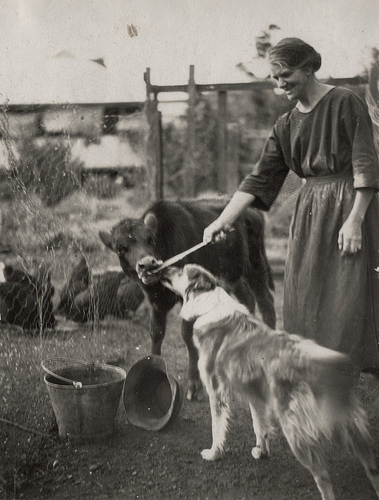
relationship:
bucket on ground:
[40, 354, 125, 441] [35, 427, 223, 497]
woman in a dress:
[200, 37, 377, 375] [236, 83, 378, 373]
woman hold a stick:
[200, 37, 377, 375] [143, 238, 219, 296]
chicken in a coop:
[67, 272, 124, 322] [8, 210, 144, 356]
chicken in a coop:
[112, 277, 145, 318] [8, 210, 144, 356]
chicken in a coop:
[53, 256, 94, 317] [8, 210, 144, 356]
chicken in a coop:
[0, 262, 60, 296] [8, 210, 144, 356]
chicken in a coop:
[2, 275, 53, 329] [8, 210, 144, 356]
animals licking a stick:
[159, 262, 378, 499] [152, 237, 227, 290]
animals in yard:
[159, 262, 378, 499] [81, 420, 246, 494]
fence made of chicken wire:
[77, 36, 250, 149] [18, 223, 146, 339]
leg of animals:
[196, 383, 235, 464] [159, 262, 378, 499]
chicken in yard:
[0, 281, 58, 333] [4, 199, 156, 379]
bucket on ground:
[40, 354, 125, 441] [31, 449, 201, 486]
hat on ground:
[124, 352, 183, 428] [31, 449, 201, 486]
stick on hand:
[153, 228, 235, 275] [198, 220, 231, 247]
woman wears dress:
[199, 28, 377, 423] [280, 178, 377, 358]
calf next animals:
[98, 198, 276, 400] [159, 262, 378, 499]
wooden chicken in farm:
[147, 83, 275, 205] [0, 33, 374, 498]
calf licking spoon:
[86, 188, 277, 382] [147, 226, 236, 275]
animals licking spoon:
[159, 262, 378, 499] [147, 226, 236, 275]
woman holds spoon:
[200, 37, 377, 375] [150, 225, 237, 275]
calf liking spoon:
[98, 198, 276, 400] [145, 222, 238, 276]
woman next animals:
[200, 37, 377, 375] [95, 190, 378, 498]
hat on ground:
[123, 355, 184, 433] [1, 249, 377, 497]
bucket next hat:
[40, 354, 125, 441] [123, 355, 184, 433]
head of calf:
[87, 213, 170, 291] [98, 198, 276, 400]